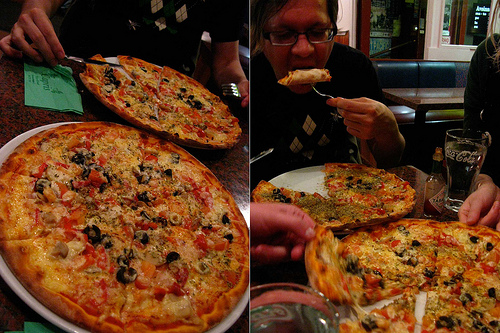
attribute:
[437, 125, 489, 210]
glass — large, clear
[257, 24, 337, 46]
glasses — black, framed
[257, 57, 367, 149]
sweater — black, white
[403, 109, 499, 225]
cup — glass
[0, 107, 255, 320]
pizza — slice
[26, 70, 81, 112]
napkin — green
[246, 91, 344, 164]
shirt — black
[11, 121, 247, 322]
pizza — large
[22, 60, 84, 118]
napkin — green, colored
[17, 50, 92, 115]
envelope — green